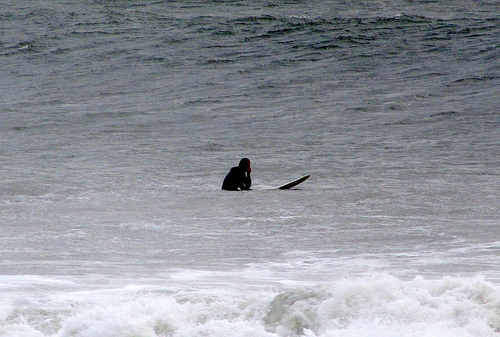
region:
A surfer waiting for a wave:
[211, 146, 316, 200]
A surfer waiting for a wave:
[214, 153, 314, 200]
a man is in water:
[196, 129, 311, 269]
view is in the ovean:
[118, 152, 364, 334]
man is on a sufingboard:
[207, 115, 325, 230]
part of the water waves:
[206, 293, 318, 335]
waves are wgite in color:
[251, 269, 356, 336]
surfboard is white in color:
[281, 162, 319, 196]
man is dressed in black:
[213, 158, 259, 228]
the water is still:
[304, 40, 388, 104]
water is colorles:
[139, 32, 202, 123]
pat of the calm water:
[94, 222, 184, 287]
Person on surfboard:
[193, 141, 319, 217]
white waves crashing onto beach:
[136, 267, 387, 332]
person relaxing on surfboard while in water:
[198, 148, 321, 210]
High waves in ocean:
[151, 9, 478, 146]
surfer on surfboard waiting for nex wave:
[212, 153, 315, 198]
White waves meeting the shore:
[211, 195, 440, 333]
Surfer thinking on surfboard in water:
[199, 155, 318, 211]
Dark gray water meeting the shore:
[311, 14, 497, 319]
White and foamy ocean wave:
[196, 266, 333, 336]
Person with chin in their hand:
[209, 146, 262, 195]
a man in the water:
[190, 98, 280, 215]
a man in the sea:
[171, 104, 323, 237]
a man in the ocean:
[186, 138, 446, 299]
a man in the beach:
[145, 98, 366, 265]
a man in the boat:
[173, 121, 357, 254]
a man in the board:
[183, 120, 409, 303]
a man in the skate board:
[167, 85, 354, 292]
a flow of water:
[223, 221, 418, 332]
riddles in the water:
[369, 110, 437, 191]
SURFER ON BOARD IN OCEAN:
[214, 148, 316, 206]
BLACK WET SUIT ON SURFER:
[210, 169, 252, 190]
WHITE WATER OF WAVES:
[269, 285, 371, 331]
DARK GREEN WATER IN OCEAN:
[191, 34, 353, 84]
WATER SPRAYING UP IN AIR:
[298, 255, 376, 285]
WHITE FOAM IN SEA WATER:
[174, 251, 294, 280]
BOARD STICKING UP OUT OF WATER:
[278, 160, 310, 200]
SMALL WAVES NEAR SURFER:
[350, 99, 449, 151]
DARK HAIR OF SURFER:
[233, 149, 265, 170]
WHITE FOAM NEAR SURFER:
[253, 176, 278, 191]